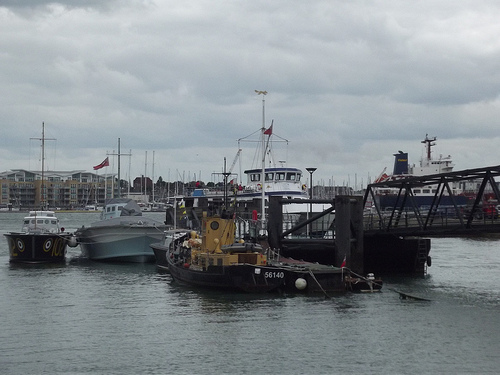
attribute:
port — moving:
[56, 82, 460, 374]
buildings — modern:
[0, 172, 133, 212]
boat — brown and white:
[3, 120, 73, 267]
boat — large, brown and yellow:
[163, 186, 306, 306]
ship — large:
[203, 116, 330, 238]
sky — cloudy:
[4, 12, 489, 133]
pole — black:
[102, 128, 147, 208]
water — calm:
[83, 306, 213, 368]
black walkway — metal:
[337, 150, 487, 251]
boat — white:
[79, 149, 166, 256]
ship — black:
[140, 183, 387, 306]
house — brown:
[0, 171, 129, 214]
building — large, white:
[5, 172, 120, 209]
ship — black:
[6, 207, 70, 263]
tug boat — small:
[161, 215, 348, 295]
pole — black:
[260, 92, 268, 237]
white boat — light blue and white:
[73, 215, 173, 272]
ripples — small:
[62, 279, 187, 359]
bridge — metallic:
[362, 166, 498, 238]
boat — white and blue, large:
[362, 126, 483, 214]